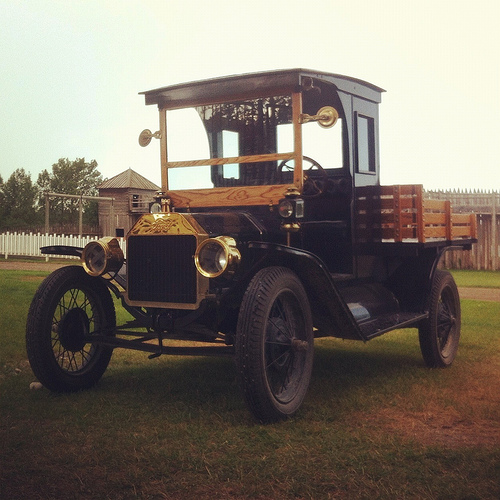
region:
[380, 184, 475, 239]
brown slats of a wooden tailgate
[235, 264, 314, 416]
thin black antique car tire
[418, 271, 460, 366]
thin black antique car tire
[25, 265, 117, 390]
thin black antique car tire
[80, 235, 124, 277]
brass vintage car headlight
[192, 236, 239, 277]
brass vintage car headlight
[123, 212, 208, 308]
brass vintage car front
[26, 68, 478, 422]
antique black car with gold and wooden accents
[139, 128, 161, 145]
brass vintage car mirror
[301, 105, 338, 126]
brass vintage car mirror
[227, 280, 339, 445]
the left wheel of an old car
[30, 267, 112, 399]
the right wheel of an old car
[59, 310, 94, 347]
the tire plate of an old car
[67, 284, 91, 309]
the spokes of an old car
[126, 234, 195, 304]
the grill of an old car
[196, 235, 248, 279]
the left headlight of an old car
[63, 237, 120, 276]
the right headlight of an old car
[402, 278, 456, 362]
the back wheel of an old car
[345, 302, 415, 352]
the step of an old car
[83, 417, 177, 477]
a small patch of green grass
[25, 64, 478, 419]
an old fashioned truck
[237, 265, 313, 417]
the tire is black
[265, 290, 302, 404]
the spokes are black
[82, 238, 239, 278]
headlights of the truck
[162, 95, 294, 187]
front window of truck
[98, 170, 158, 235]
a wood tower like building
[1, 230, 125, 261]
a white picket fence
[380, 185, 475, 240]
wood slats on truck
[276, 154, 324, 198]
steering wheel of truck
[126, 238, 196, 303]
grill on front of truck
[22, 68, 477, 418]
The vehicle is a vintage truck.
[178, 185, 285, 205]
The vehicle has wooden touches.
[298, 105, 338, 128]
The vehicle has a gold toned side mirror.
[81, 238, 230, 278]
The vehicle has two headlights.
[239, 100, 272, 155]
The vehicle has a curtain.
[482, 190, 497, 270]
A fence is in the background.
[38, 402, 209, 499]
The ground is covered with grass.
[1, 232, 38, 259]
A white fence is in the background.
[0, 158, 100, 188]
Trees are in the background.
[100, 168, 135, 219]
A building is in the background.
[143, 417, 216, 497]
The grass is patchy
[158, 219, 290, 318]
The light is off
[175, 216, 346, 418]
The wheel is round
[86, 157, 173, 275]
A building is in the back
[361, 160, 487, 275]
The back of the truck is wooden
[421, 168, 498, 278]
The fence is in the back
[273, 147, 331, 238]
The steering wheel is round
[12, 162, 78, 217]
The leaves are green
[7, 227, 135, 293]
The fence is white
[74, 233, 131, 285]
The light is shiny